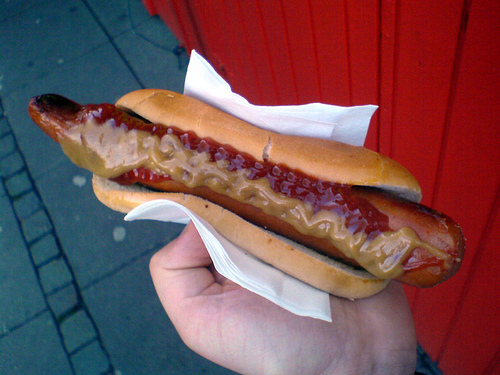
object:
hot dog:
[11, 64, 471, 309]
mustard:
[86, 125, 419, 237]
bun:
[114, 78, 421, 198]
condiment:
[189, 166, 277, 209]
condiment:
[134, 135, 246, 161]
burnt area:
[23, 84, 76, 124]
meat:
[20, 88, 475, 289]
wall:
[232, 4, 492, 138]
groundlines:
[0, 108, 109, 373]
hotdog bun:
[87, 87, 421, 301]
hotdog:
[25, 86, 462, 297]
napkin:
[122, 50, 378, 324]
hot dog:
[62, 55, 488, 217]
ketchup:
[259, 163, 381, 215]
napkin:
[167, 63, 398, 144]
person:
[147, 217, 419, 374]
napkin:
[177, 47, 379, 136]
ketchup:
[75, 99, 379, 228]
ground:
[2, 222, 36, 371]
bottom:
[97, 210, 456, 289]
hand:
[129, 213, 437, 373]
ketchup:
[92, 107, 175, 124]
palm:
[170, 257, 423, 363]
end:
[343, 155, 452, 310]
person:
[116, 1, 497, 372]